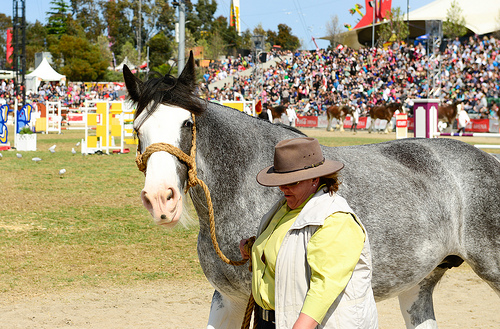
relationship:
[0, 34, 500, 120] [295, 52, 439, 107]
crowd sitting stands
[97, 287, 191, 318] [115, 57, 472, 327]
sand beside horse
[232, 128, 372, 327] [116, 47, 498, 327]
woman walking horse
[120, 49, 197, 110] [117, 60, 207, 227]
black hair on head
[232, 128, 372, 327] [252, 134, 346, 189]
woman wearing hat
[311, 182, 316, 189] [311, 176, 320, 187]
earring on ear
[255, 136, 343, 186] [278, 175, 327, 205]
hat on head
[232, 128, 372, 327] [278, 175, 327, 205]
woman has head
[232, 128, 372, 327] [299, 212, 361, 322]
woman has sleeve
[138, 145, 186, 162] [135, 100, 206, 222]
rope on face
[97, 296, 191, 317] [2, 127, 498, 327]
sand on ground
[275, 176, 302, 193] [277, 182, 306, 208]
sunglasses on face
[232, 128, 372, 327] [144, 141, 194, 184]
woman with rope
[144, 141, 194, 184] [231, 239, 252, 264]
rope in her hand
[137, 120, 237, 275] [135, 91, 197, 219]
rope on face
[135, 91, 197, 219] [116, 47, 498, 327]
face of horse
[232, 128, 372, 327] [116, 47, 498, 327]
woman behind horse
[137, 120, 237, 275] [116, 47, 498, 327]
rope on horse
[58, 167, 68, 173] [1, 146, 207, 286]
white pigeon on ground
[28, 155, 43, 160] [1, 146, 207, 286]
white pigeon on ground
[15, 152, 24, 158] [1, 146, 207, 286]
white pigeon on ground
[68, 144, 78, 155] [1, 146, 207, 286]
white pigeon on ground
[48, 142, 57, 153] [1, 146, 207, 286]
white pigeon on ground